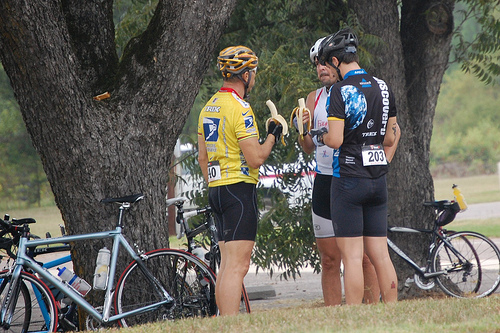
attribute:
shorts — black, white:
[308, 171, 339, 243]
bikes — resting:
[0, 195, 220, 326]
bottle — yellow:
[449, 182, 471, 210]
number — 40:
[368, 153, 388, 167]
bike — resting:
[353, 191, 498, 300]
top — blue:
[53, 265, 66, 275]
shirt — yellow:
[195, 90, 259, 187]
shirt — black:
[324, 70, 398, 178]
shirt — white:
[308, 84, 344, 176]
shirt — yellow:
[188, 82, 269, 191]